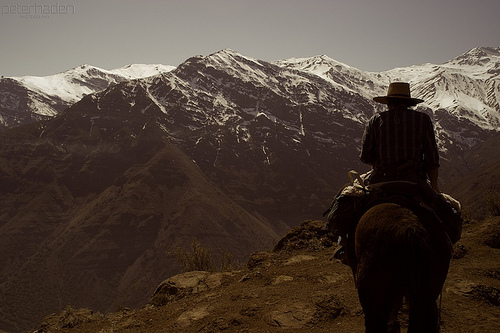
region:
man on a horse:
[327, 73, 455, 323]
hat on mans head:
[373, 79, 421, 109]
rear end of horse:
[355, 200, 454, 331]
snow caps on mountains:
[5, 45, 498, 164]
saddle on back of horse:
[324, 168, 469, 227]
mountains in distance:
[7, 36, 481, 284]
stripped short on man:
[360, 108, 442, 174]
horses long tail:
[404, 235, 442, 328]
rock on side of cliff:
[155, 268, 230, 299]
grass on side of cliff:
[179, 242, 241, 270]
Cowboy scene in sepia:
[1, 0, 499, 330]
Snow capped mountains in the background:
[1, 37, 497, 99]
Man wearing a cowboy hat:
[324, 74, 472, 247]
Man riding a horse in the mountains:
[323, 50, 470, 330]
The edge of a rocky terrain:
[115, 214, 336, 314]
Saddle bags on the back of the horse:
[322, 165, 472, 242]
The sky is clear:
[1, 0, 499, 79]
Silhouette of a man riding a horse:
[317, 68, 469, 331]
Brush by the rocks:
[155, 238, 275, 284]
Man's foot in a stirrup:
[327, 237, 356, 265]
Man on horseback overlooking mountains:
[25, 37, 471, 284]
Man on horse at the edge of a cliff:
[111, 90, 468, 315]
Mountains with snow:
[5, 12, 372, 137]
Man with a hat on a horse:
[337, 70, 454, 247]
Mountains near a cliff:
[18, 121, 333, 318]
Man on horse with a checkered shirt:
[348, 60, 448, 233]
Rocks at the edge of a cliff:
[21, 206, 326, 328]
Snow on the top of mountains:
[0, 23, 495, 80]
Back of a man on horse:
[311, 48, 461, 280]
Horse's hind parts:
[160, 190, 475, 322]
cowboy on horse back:
[335, 79, 462, 329]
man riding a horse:
[326, 82, 462, 328]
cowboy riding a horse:
[332, 82, 460, 329]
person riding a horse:
[341, 80, 456, 329]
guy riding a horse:
[334, 80, 459, 330]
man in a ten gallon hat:
[338, 79, 472, 331]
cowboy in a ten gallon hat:
[342, 84, 465, 323]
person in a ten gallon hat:
[335, 82, 460, 327]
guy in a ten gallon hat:
[334, 82, 463, 320]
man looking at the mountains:
[334, 80, 463, 326]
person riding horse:
[317, 66, 470, 331]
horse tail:
[385, 225, 450, 327]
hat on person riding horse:
[363, 73, 429, 108]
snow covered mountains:
[3, 41, 498, 304]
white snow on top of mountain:
[2, 70, 78, 110]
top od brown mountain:
[19, 173, 498, 330]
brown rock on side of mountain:
[153, 262, 238, 304]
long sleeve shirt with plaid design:
[353, 103, 444, 187]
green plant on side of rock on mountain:
[174, 238, 219, 275]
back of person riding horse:
[315, 63, 474, 331]